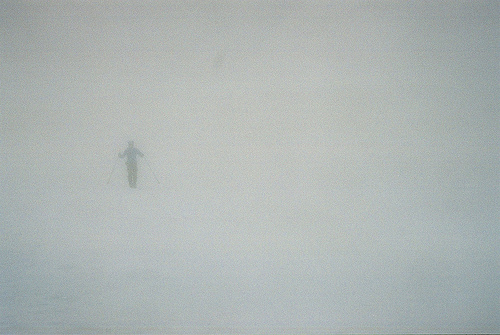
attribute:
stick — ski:
[141, 158, 158, 188]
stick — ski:
[104, 156, 121, 185]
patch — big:
[192, 146, 377, 280]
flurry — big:
[209, 25, 397, 128]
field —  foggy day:
[116, 52, 254, 249]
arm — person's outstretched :
[116, 139, 150, 168]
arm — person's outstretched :
[109, 134, 149, 162]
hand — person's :
[112, 152, 152, 162]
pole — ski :
[100, 128, 119, 185]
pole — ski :
[97, 147, 126, 184]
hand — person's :
[108, 139, 148, 173]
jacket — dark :
[119, 145, 148, 161]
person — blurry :
[117, 136, 154, 183]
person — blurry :
[116, 138, 159, 192]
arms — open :
[111, 135, 149, 165]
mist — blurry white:
[209, 34, 359, 107]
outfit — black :
[116, 155, 142, 175]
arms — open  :
[111, 139, 148, 163]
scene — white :
[23, 28, 460, 320]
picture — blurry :
[20, 60, 451, 324]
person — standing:
[114, 130, 152, 186]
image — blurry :
[6, 14, 482, 324]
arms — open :
[108, 142, 148, 162]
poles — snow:
[85, 137, 174, 172]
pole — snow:
[137, 143, 167, 189]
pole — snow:
[100, 157, 130, 197]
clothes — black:
[119, 145, 152, 194]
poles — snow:
[97, 151, 141, 196]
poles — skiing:
[92, 153, 156, 163]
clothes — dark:
[124, 150, 167, 210]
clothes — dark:
[108, 149, 164, 189]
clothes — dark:
[127, 156, 149, 186]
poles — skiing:
[109, 156, 153, 186]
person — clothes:
[101, 132, 159, 209]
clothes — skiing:
[116, 150, 157, 202]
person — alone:
[113, 140, 157, 199]